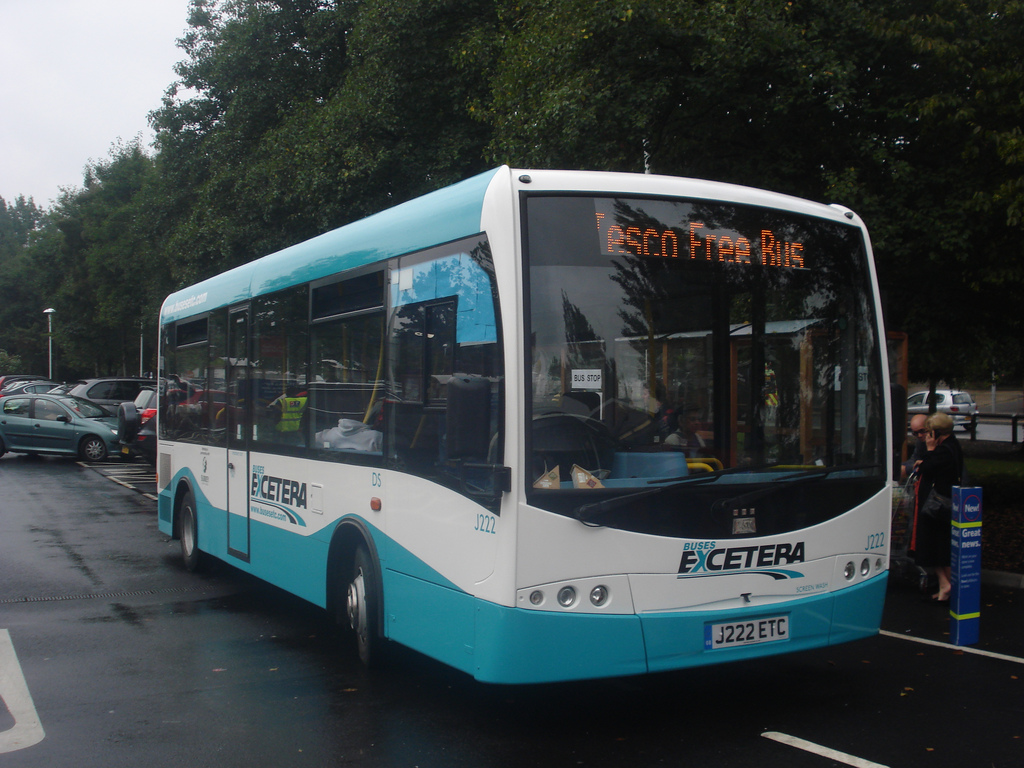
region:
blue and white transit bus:
[98, 139, 905, 697]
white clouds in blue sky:
[4, 35, 27, 65]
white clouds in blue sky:
[51, 29, 93, 53]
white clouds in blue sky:
[133, 28, 163, 52]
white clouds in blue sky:
[1, 76, 58, 134]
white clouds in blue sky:
[16, 107, 62, 181]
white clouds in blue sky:
[86, 37, 150, 104]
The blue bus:
[124, 159, 919, 701]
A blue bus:
[121, 149, 897, 696]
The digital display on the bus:
[589, 202, 820, 279]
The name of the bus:
[665, 531, 812, 579]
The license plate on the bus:
[701, 601, 796, 646]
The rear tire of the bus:
[163, 487, 220, 570]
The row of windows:
[140, 259, 511, 501]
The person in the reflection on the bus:
[264, 376, 321, 449]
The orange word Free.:
[687, 219, 751, 265]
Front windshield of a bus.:
[522, 197, 887, 488]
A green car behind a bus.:
[3, 390, 124, 466]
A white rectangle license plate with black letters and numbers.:
[709, 611, 790, 647]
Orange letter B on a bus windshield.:
[757, 226, 776, 271]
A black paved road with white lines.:
[5, 454, 1020, 765]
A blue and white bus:
[156, 163, 891, 689]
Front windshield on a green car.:
[63, 396, 105, 422]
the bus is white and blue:
[126, 156, 927, 725]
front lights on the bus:
[503, 551, 892, 632]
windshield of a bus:
[503, 161, 903, 548]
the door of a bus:
[204, 296, 274, 571]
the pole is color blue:
[932, 466, 1002, 669]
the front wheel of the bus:
[313, 511, 406, 702]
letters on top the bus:
[572, 200, 822, 283]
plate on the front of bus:
[695, 590, 803, 667]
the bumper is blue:
[468, 562, 896, 703]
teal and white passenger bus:
[146, 154, 906, 686]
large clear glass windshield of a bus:
[516, 186, 890, 548]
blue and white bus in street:
[143, 159, 900, 694]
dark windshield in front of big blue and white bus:
[526, 184, 885, 551]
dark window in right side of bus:
[143, 237, 502, 509]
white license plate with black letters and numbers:
[709, 614, 798, 652]